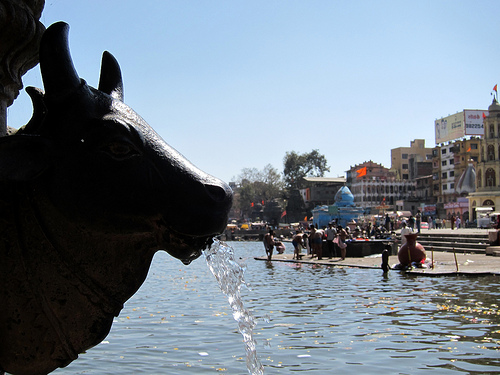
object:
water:
[196, 235, 274, 375]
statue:
[0, 18, 237, 374]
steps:
[413, 231, 491, 253]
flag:
[355, 165, 370, 178]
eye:
[99, 131, 141, 161]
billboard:
[431, 110, 467, 144]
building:
[429, 136, 482, 226]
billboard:
[461, 106, 489, 137]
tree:
[280, 146, 329, 210]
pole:
[406, 245, 413, 271]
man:
[261, 229, 282, 261]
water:
[150, 277, 499, 374]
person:
[291, 230, 309, 261]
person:
[310, 227, 326, 261]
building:
[464, 84, 499, 228]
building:
[346, 174, 418, 214]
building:
[294, 175, 350, 220]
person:
[335, 224, 351, 261]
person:
[379, 246, 392, 278]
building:
[309, 184, 367, 228]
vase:
[398, 230, 430, 268]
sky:
[6, 0, 498, 146]